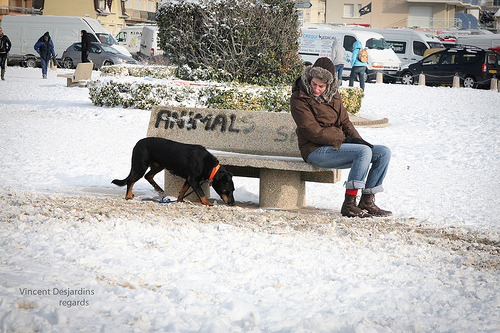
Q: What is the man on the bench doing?
A: Watching the dog.